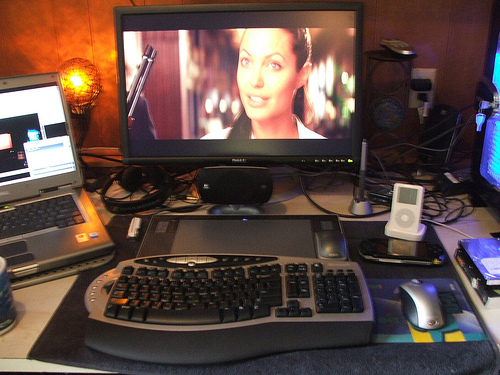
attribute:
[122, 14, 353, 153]
movie — playing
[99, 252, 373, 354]
computer keyboard — black, silver, grey, independent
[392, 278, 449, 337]
wireless mouse — black, silver, optical, blue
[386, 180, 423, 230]
ipod — white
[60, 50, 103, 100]
light — glowing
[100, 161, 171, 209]
headphones — black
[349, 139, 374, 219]
microphone — silver, black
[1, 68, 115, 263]
laptop — small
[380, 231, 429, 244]
dock — small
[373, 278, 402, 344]
mouse pad — multi-colored